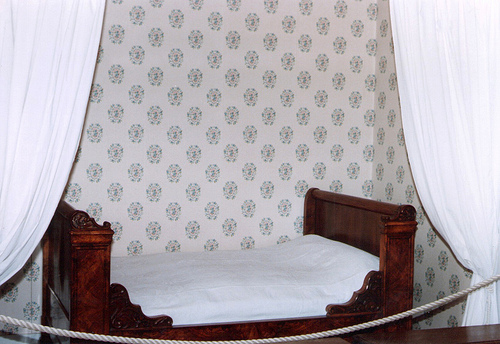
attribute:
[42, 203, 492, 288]
furniture — displayed, behind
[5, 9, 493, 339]
wallpaper — white, green, patterned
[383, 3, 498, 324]
curtain — white, pulled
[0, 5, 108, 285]
curtain — white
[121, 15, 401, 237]
wallpaper — patterned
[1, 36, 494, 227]
cloth — two screen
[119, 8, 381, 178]
wallpaper — patterned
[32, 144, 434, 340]
bed — white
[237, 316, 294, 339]
rope — long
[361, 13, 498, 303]
curtain — white, hanging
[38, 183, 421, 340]
furniture — carved, woodwork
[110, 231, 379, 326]
sheet — white, creased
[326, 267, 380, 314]
wooden piece — decorated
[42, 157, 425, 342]
bed — wooden, white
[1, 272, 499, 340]
rope — white, hanging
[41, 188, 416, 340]
bed — wood, dark, white, old, wooden, brown, small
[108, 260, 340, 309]
sheet — white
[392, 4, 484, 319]
drape — white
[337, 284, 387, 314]
carving — fancy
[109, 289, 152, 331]
carving — fancy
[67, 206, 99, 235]
carving — fancy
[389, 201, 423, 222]
carving — fancy